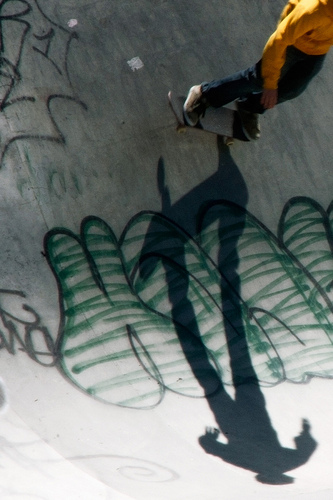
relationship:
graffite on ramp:
[0, 1, 332, 485] [1, 0, 332, 467]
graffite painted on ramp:
[31, 26, 63, 78] [1, 0, 332, 467]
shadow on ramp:
[148, 143, 309, 486] [1, 0, 332, 467]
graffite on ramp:
[31, 26, 63, 78] [1, 0, 332, 467]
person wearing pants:
[193, 0, 330, 135] [200, 44, 310, 124]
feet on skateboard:
[181, 82, 206, 126] [166, 89, 256, 145]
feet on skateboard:
[235, 98, 261, 141] [166, 89, 256, 145]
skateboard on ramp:
[167, 85, 263, 144] [13, 54, 323, 373]